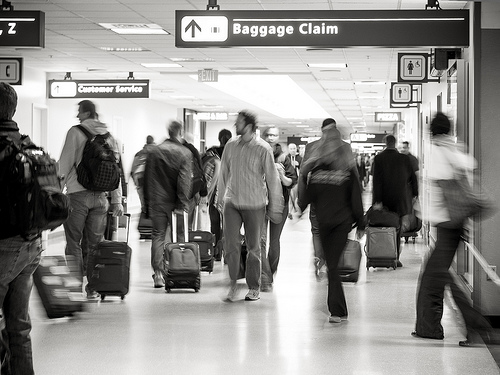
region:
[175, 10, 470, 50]
Sign for baggage claim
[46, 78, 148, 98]
Sign for customer service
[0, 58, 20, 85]
Sign for telephones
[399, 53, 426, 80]
Ladies restroom sign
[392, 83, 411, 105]
Sign for mens restroom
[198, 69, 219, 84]
Exit sign pointing left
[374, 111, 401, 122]
Sign for "PIZZA" shop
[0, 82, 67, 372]
Passenger at left in jeans wearing backpack without rolling luggage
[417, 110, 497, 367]
Female passenger entering frame from right with rolling luggage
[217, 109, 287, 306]
Beared male in center with no visible luggage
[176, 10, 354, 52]
Baggage claim sign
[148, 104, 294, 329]
Travelers in an airport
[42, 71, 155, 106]
Customer service sign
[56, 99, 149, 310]
A traveler with luggage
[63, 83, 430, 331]
Black and white image of people in an airport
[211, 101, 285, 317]
Man with a beard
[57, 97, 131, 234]
Man wearing a backpack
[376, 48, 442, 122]
Signs for male and female restrooms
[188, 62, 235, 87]
Exit sign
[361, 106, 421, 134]
Sign for pizza in an airport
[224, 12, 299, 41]
The word Baggage on the sign.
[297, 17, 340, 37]
The word Claim on the sign.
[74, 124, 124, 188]
The man in a light colored jacket with a black back pack on the left.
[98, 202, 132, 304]
The rolling suitcase the man with the light colored jacket on is holding.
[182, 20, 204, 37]
The black arrow on the sign that reads Baggage Claim.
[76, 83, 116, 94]
The word Customer on the sign on the left.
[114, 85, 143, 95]
The word Service on the sign on the left.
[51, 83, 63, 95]
The arrow on the sign that reads Customer Service.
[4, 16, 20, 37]
The letter Z on the black sign on the left.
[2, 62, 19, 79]
The telephone sign behind the sign with the Z on the left.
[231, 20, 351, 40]
Sign that says Baggage Claim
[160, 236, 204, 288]
Wheelie bag of man in background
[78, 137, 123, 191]
Man carrying black book bag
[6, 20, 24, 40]
Sign that has a Z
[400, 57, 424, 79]
White sign for women's restroom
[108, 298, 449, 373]
White floor is glossy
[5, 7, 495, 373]
This scene takes place in an airport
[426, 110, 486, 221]
Man wearing hoodie and long pants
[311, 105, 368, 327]
Woman walking towards the observer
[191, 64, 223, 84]
Glowing exit sign on ceiling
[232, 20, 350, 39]
baggage claim on a sign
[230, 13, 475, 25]
a long white line on a sign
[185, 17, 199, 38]
an arrow pointing up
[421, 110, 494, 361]
a blurred woman walking out of a doorway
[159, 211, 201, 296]
a dark suitcase being rolled on the floor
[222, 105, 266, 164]
a man with a beard looking left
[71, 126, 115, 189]
a black backpack on a man's back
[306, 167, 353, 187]
blurred white writing on a woman's sweater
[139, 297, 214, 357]
shiny white floor in an airport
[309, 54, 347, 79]
lights in the ceiling